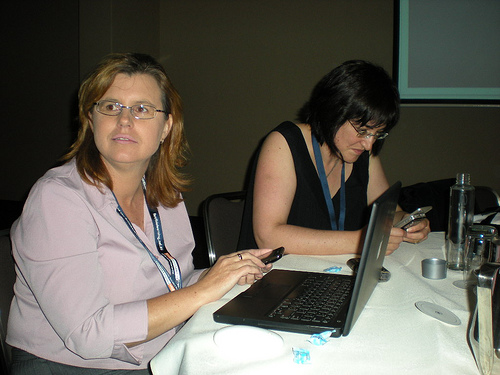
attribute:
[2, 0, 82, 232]
wall — tan